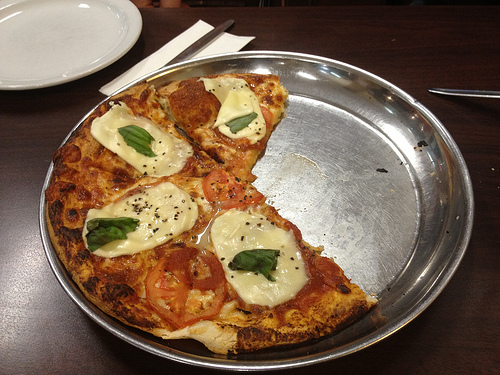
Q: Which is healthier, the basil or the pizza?
A: The basil is healthier than the pizza.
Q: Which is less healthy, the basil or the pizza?
A: The pizza is less healthy than the basil.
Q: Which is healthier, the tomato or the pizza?
A: The tomato is healthier than the pizza.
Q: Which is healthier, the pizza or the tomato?
A: The tomato is healthier than the pizza.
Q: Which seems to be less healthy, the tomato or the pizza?
A: The pizza is less healthy than the tomato.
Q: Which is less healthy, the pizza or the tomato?
A: The pizza is less healthy than the tomato.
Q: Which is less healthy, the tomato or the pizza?
A: The pizza is less healthy than the tomato.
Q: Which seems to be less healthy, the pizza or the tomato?
A: The pizza is less healthy than the tomato.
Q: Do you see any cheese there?
A: Yes, there is cheese.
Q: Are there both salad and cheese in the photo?
A: No, there is cheese but no salad.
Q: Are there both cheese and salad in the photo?
A: No, there is cheese but no salad.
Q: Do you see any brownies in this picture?
A: No, there are no brownies.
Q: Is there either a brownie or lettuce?
A: No, there are no brownies or lettuce.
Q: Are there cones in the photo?
A: No, there are no cones.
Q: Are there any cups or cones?
A: No, there are no cones or cups.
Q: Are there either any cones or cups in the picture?
A: No, there are no cones or cups.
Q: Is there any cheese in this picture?
A: Yes, there is cheese.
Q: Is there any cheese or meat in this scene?
A: Yes, there is cheese.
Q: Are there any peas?
A: No, there are no peas.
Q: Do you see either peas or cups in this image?
A: No, there are no peas or cups.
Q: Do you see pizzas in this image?
A: Yes, there is a pizza.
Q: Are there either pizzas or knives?
A: Yes, there is a pizza.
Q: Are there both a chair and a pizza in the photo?
A: No, there is a pizza but no chairs.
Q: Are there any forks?
A: No, there are no forks.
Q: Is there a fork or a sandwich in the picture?
A: No, there are no forks or sandwiches.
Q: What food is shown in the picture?
A: The food is a pizza.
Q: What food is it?
A: The food is a pizza.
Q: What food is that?
A: This is a pizza.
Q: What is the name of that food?
A: This is a pizza.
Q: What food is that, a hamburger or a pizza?
A: This is a pizza.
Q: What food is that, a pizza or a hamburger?
A: This is a pizza.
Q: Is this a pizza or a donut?
A: This is a pizza.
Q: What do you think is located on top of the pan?
A: The pizza is on top of the pan.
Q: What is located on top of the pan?
A: The pizza is on top of the pan.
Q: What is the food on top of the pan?
A: The food is a pizza.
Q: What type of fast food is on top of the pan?
A: The food is a pizza.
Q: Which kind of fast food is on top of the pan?
A: The food is a pizza.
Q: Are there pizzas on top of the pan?
A: Yes, there is a pizza on top of the pan.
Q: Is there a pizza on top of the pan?
A: Yes, there is a pizza on top of the pan.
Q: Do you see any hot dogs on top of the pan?
A: No, there is a pizza on top of the pan.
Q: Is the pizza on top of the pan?
A: Yes, the pizza is on top of the pan.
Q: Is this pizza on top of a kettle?
A: No, the pizza is on top of the pan.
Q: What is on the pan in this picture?
A: The pizza is on the pan.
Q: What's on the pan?
A: The pizza is on the pan.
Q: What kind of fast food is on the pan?
A: The food is a pizza.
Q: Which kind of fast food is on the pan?
A: The food is a pizza.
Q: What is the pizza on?
A: The pizza is on the pan.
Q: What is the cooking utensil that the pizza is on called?
A: The cooking utensil is a pan.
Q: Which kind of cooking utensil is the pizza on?
A: The pizza is on the pan.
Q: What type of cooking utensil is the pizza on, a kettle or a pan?
A: The pizza is on a pan.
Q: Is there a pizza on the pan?
A: Yes, there is a pizza on the pan.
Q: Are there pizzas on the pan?
A: Yes, there is a pizza on the pan.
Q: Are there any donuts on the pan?
A: No, there is a pizza on the pan.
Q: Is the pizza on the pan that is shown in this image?
A: Yes, the pizza is on the pan.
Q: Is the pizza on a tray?
A: No, the pizza is on the pan.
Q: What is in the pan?
A: The pizza is in the pan.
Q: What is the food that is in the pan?
A: The food is a pizza.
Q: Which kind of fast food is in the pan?
A: The food is a pizza.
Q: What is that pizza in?
A: The pizza is in the pan.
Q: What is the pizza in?
A: The pizza is in the pan.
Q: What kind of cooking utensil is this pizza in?
A: The pizza is in the pan.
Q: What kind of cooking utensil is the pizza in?
A: The pizza is in the pan.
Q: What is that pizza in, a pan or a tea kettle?
A: The pizza is in a pan.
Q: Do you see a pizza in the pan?
A: Yes, there is a pizza in the pan.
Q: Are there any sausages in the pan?
A: No, there is a pizza in the pan.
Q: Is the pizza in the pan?
A: Yes, the pizza is in the pan.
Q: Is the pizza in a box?
A: No, the pizza is in the pan.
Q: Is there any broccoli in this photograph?
A: No, there is no broccoli.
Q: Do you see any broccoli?
A: No, there is no broccoli.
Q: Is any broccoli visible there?
A: No, there is no broccoli.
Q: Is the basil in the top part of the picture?
A: No, the basil is in the bottom of the image.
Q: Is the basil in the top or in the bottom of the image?
A: The basil is in the bottom of the image.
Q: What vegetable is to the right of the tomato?
A: The vegetable is basil.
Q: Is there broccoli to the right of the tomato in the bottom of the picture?
A: No, there is basil to the right of the tomato.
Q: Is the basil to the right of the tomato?
A: Yes, the basil is to the right of the tomato.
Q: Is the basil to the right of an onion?
A: No, the basil is to the right of the tomato.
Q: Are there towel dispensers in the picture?
A: No, there are no towel dispensers.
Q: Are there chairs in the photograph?
A: No, there are no chairs.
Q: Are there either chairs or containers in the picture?
A: No, there are no chairs or containers.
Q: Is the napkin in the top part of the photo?
A: Yes, the napkin is in the top of the image.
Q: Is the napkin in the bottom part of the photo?
A: No, the napkin is in the top of the image.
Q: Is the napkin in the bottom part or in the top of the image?
A: The napkin is in the top of the image.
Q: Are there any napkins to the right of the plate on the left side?
A: Yes, there is a napkin to the right of the plate.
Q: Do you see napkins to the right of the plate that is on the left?
A: Yes, there is a napkin to the right of the plate.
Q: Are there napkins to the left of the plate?
A: No, the napkin is to the right of the plate.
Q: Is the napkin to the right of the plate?
A: Yes, the napkin is to the right of the plate.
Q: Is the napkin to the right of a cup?
A: No, the napkin is to the right of the plate.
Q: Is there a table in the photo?
A: Yes, there is a table.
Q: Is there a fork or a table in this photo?
A: Yes, there is a table.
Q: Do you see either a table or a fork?
A: Yes, there is a table.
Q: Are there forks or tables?
A: Yes, there is a table.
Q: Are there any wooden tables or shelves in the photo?
A: Yes, there is a wood table.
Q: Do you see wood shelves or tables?
A: Yes, there is a wood table.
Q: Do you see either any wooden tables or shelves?
A: Yes, there is a wood table.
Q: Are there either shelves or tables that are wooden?
A: Yes, the table is wooden.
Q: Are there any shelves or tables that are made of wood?
A: Yes, the table is made of wood.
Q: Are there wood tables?
A: Yes, there is a table that is made of wood.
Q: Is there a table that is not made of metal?
A: Yes, there is a table that is made of wood.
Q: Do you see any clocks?
A: No, there are no clocks.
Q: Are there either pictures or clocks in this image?
A: No, there are no clocks or pictures.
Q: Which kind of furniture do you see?
A: The furniture is a table.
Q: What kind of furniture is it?
A: The piece of furniture is a table.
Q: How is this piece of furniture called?
A: That is a table.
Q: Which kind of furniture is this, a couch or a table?
A: That is a table.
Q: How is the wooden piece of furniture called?
A: The piece of furniture is a table.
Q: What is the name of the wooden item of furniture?
A: The piece of furniture is a table.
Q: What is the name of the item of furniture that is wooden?
A: The piece of furniture is a table.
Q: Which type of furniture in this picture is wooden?
A: The furniture is a table.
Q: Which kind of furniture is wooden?
A: The furniture is a table.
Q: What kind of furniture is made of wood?
A: The furniture is a table.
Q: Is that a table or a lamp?
A: That is a table.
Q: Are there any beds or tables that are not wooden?
A: No, there is a table but it is wooden.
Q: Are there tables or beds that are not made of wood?
A: No, there is a table but it is made of wood.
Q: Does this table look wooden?
A: Yes, the table is wooden.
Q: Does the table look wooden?
A: Yes, the table is wooden.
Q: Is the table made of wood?
A: Yes, the table is made of wood.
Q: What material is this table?
A: The table is made of wood.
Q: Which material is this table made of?
A: The table is made of wood.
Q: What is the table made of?
A: The table is made of wood.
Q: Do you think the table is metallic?
A: No, the table is wooden.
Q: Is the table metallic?
A: No, the table is wooden.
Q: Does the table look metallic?
A: No, the table is wooden.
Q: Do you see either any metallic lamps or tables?
A: No, there is a table but it is wooden.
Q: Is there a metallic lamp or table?
A: No, there is a table but it is wooden.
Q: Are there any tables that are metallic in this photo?
A: No, there is a table but it is wooden.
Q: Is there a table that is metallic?
A: No, there is a table but it is wooden.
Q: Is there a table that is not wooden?
A: No, there is a table but it is wooden.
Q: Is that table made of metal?
A: No, the table is made of wood.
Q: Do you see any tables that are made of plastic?
A: No, there is a table but it is made of wood.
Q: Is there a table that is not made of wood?
A: No, there is a table but it is made of wood.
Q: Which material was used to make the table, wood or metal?
A: The table is made of wood.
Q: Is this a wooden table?
A: Yes, this is a wooden table.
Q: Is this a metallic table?
A: No, this is a wooden table.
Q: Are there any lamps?
A: No, there are no lamps.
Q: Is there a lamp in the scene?
A: No, there are no lamps.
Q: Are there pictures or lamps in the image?
A: No, there are no lamps or pictures.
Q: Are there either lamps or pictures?
A: No, there are no lamps or pictures.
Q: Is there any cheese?
A: Yes, there is cheese.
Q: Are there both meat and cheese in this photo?
A: No, there is cheese but no meat.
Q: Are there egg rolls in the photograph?
A: No, there are no egg rolls.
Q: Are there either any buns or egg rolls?
A: No, there are no egg rolls or buns.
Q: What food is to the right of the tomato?
A: The food is cheese.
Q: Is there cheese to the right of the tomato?
A: Yes, there is cheese to the right of the tomato.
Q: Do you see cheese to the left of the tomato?
A: No, the cheese is to the right of the tomato.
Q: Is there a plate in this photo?
A: Yes, there is a plate.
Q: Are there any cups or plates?
A: Yes, there is a plate.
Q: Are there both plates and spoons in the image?
A: No, there is a plate but no spoons.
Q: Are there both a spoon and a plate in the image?
A: No, there is a plate but no spoons.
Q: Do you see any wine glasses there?
A: No, there are no wine glasses.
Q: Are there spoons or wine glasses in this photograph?
A: No, there are no wine glasses or spoons.